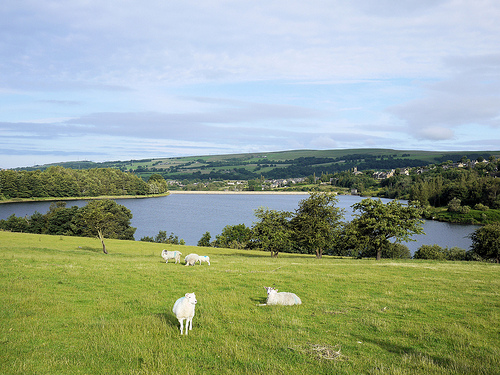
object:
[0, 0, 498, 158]
clouds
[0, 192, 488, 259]
lake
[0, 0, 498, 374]
background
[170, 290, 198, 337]
lamb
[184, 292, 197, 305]
head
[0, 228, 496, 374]
grass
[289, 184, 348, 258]
tree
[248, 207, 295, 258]
tree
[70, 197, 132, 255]
tree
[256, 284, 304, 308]
lamb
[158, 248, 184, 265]
lambs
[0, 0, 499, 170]
sky